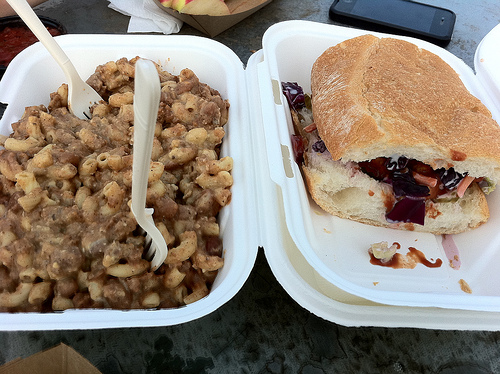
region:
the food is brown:
[14, 76, 152, 289]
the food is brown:
[27, 111, 109, 253]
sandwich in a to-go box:
[295, 39, 486, 296]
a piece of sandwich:
[295, 42, 496, 290]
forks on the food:
[37, 37, 194, 302]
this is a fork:
[126, 73, 166, 238]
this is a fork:
[37, 19, 94, 96]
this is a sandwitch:
[308, 70, 490, 248]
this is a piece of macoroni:
[0, 284, 35, 307]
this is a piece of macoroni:
[31, 284, 50, 304]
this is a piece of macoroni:
[172, 234, 199, 265]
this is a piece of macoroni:
[0, 133, 33, 155]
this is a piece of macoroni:
[19, 168, 37, 205]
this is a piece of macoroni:
[179, 125, 202, 160]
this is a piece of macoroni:
[179, 94, 209, 120]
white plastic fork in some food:
[122, 58, 176, 283]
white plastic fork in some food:
[2, 3, 111, 125]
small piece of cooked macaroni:
[165, 226, 200, 268]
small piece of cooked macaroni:
[97, 175, 125, 220]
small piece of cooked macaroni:
[198, 152, 238, 177]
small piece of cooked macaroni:
[195, 168, 232, 192]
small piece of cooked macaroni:
[0, 274, 37, 311]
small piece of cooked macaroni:
[10, 167, 45, 217]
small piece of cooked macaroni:
[0, 131, 41, 156]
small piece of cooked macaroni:
[43, 160, 78, 181]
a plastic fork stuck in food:
[110, 54, 211, 281]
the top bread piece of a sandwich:
[317, 33, 499, 178]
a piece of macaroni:
[12, 161, 56, 214]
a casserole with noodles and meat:
[19, 152, 126, 285]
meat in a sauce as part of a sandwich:
[375, 159, 472, 204]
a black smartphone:
[328, 4, 460, 45]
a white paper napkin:
[97, 6, 187, 37]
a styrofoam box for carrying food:
[206, 38, 327, 303]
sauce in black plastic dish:
[3, 12, 70, 73]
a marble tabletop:
[201, 330, 321, 370]